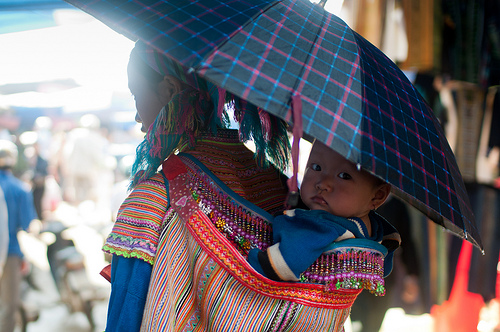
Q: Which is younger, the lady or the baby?
A: The baby is younger than the lady.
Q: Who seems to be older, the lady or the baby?
A: The lady is older than the baby.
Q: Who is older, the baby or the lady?
A: The lady is older than the baby.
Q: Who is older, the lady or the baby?
A: The lady is older than the baby.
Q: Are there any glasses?
A: No, there are no glasses.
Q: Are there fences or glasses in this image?
A: No, there are no glasses or fences.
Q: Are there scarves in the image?
A: Yes, there is a scarf.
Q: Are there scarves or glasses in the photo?
A: Yes, there is a scarf.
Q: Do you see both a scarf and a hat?
A: No, there is a scarf but no hats.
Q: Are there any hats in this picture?
A: No, there are no hats.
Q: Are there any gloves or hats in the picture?
A: No, there are no hats or gloves.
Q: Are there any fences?
A: No, there are no fences.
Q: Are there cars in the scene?
A: No, there are no cars.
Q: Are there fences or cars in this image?
A: No, there are no cars or fences.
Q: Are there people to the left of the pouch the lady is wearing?
A: Yes, there are people to the left of the pouch.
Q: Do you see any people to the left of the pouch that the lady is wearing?
A: Yes, there are people to the left of the pouch.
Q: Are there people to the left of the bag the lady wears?
A: Yes, there are people to the left of the pouch.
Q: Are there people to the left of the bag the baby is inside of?
A: Yes, there are people to the left of the bag.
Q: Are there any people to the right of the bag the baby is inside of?
A: No, the people are to the left of the bag.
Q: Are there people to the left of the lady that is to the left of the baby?
A: Yes, there are people to the left of the lady.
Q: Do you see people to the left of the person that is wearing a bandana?
A: Yes, there are people to the left of the lady.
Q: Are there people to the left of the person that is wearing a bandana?
A: Yes, there are people to the left of the lady.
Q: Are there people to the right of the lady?
A: No, the people are to the left of the lady.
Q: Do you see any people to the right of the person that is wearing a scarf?
A: No, the people are to the left of the lady.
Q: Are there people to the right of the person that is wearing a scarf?
A: No, the people are to the left of the lady.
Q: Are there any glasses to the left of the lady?
A: No, there are people to the left of the lady.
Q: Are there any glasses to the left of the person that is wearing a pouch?
A: No, there are people to the left of the lady.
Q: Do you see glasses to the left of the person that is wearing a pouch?
A: No, there are people to the left of the lady.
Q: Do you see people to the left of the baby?
A: Yes, there are people to the left of the baby.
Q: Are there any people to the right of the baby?
A: No, the people are to the left of the baby.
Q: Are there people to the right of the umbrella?
A: No, the people are to the left of the umbrella.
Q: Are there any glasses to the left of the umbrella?
A: No, there are people to the left of the umbrella.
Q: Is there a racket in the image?
A: No, there are no rackets.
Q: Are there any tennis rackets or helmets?
A: No, there are no tennis rackets or helmets.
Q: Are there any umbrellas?
A: Yes, there is an umbrella.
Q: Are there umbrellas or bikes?
A: Yes, there is an umbrella.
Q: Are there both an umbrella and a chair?
A: No, there is an umbrella but no chairs.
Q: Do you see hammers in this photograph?
A: No, there are no hammers.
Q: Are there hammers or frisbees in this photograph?
A: No, there are no hammers or frisbees.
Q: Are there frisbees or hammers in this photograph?
A: No, there are no hammers or frisbees.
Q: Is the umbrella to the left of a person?
A: No, the umbrella is to the right of a person.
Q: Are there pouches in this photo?
A: Yes, there is a pouch.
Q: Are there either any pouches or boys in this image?
A: Yes, there is a pouch.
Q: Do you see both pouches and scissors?
A: No, there is a pouch but no scissors.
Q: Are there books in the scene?
A: No, there are no books.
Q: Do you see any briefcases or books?
A: No, there are no books or briefcases.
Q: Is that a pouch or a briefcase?
A: That is a pouch.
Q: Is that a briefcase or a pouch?
A: That is a pouch.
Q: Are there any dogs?
A: No, there are no dogs.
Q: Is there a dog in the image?
A: No, there are no dogs.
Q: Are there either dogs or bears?
A: No, there are no dogs or bears.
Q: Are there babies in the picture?
A: Yes, there is a baby.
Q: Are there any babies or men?
A: Yes, there is a baby.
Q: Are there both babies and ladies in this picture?
A: Yes, there are both a baby and a lady.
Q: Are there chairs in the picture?
A: No, there are no chairs.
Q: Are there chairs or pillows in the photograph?
A: No, there are no chairs or pillows.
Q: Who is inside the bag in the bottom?
A: The baby is inside the bag.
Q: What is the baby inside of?
A: The baby is inside the bag.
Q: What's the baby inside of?
A: The baby is inside the bag.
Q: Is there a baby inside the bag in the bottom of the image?
A: Yes, there is a baby inside the bag.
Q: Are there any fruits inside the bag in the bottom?
A: No, there is a baby inside the bag.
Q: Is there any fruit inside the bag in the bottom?
A: No, there is a baby inside the bag.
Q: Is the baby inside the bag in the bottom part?
A: Yes, the baby is inside the bag.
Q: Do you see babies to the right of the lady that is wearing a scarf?
A: Yes, there is a baby to the right of the lady.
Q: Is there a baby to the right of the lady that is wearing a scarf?
A: Yes, there is a baby to the right of the lady.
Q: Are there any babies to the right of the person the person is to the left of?
A: Yes, there is a baby to the right of the lady.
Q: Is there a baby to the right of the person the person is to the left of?
A: Yes, there is a baby to the right of the lady.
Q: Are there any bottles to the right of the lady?
A: No, there is a baby to the right of the lady.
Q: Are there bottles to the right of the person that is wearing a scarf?
A: No, there is a baby to the right of the lady.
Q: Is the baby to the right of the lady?
A: Yes, the baby is to the right of the lady.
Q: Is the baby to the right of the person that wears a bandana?
A: Yes, the baby is to the right of the lady.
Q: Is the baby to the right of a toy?
A: No, the baby is to the right of the lady.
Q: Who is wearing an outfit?
A: The baby is wearing an outfit.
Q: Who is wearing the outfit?
A: The baby is wearing an outfit.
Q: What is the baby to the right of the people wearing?
A: The baby is wearing an outfit.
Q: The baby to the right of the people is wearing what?
A: The baby is wearing an outfit.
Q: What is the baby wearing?
A: The baby is wearing an outfit.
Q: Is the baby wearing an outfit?
A: Yes, the baby is wearing an outfit.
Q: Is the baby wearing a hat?
A: No, the baby is wearing an outfit.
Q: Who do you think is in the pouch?
A: The baby is in the pouch.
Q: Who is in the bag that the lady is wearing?
A: The baby is in the pouch.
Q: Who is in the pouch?
A: The baby is in the pouch.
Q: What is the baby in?
A: The baby is in the pouch.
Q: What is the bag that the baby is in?
A: The bag is a pouch.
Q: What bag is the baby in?
A: The baby is in the pouch.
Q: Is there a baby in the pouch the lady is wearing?
A: Yes, there is a baby in the pouch.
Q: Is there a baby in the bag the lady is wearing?
A: Yes, there is a baby in the pouch.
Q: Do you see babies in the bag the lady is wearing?
A: Yes, there is a baby in the pouch.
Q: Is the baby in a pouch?
A: Yes, the baby is in a pouch.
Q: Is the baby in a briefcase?
A: No, the baby is in a pouch.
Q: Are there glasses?
A: No, there are no glasses.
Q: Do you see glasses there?
A: No, there are no glasses.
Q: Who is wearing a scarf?
A: The lady is wearing a scarf.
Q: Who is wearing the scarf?
A: The lady is wearing a scarf.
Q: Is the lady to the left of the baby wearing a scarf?
A: Yes, the lady is wearing a scarf.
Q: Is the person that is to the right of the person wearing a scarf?
A: Yes, the lady is wearing a scarf.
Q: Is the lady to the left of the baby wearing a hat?
A: No, the lady is wearing a scarf.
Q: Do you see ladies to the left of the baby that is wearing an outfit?
A: Yes, there is a lady to the left of the baby.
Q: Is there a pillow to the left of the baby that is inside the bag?
A: No, there is a lady to the left of the baby.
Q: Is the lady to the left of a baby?
A: Yes, the lady is to the left of a baby.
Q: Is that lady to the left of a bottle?
A: No, the lady is to the left of a baby.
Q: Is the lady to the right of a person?
A: Yes, the lady is to the right of a person.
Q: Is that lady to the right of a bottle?
A: No, the lady is to the right of a person.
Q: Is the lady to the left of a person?
A: No, the lady is to the right of a person.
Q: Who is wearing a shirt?
A: The lady is wearing a shirt.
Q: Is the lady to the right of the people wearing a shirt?
A: Yes, the lady is wearing a shirt.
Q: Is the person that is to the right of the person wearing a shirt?
A: Yes, the lady is wearing a shirt.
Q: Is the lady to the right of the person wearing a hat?
A: No, the lady is wearing a shirt.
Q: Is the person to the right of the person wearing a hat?
A: No, the lady is wearing a shirt.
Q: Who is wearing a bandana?
A: The lady is wearing a bandana.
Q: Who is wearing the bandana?
A: The lady is wearing a bandana.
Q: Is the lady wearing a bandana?
A: Yes, the lady is wearing a bandana.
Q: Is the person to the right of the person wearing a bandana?
A: Yes, the lady is wearing a bandana.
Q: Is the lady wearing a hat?
A: No, the lady is wearing a bandana.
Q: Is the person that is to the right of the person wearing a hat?
A: No, the lady is wearing a bandana.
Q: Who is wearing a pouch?
A: The lady is wearing a pouch.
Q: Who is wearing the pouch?
A: The lady is wearing a pouch.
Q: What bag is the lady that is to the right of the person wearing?
A: The lady is wearing a pouch.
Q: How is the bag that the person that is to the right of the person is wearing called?
A: The bag is a pouch.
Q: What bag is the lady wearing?
A: The lady is wearing a pouch.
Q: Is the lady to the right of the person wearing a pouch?
A: Yes, the lady is wearing a pouch.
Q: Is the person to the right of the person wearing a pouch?
A: Yes, the lady is wearing a pouch.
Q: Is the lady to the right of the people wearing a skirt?
A: No, the lady is wearing a pouch.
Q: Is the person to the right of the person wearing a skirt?
A: No, the lady is wearing a pouch.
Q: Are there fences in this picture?
A: No, there are no fences.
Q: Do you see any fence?
A: No, there are no fences.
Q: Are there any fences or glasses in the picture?
A: No, there are no fences or glasses.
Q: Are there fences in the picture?
A: No, there are no fences.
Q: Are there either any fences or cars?
A: No, there are no fences or cars.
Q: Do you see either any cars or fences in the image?
A: No, there are no fences or cars.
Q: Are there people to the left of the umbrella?
A: Yes, there is a person to the left of the umbrella.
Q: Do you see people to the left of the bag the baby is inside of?
A: Yes, there is a person to the left of the bag.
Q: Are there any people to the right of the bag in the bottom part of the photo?
A: No, the person is to the left of the bag.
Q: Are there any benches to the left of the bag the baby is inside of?
A: No, there is a person to the left of the bag.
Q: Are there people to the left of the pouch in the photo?
A: Yes, there is a person to the left of the pouch.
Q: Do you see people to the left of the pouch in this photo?
A: Yes, there is a person to the left of the pouch.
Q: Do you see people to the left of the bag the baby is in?
A: Yes, there is a person to the left of the pouch.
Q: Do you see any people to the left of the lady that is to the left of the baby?
A: Yes, there is a person to the left of the lady.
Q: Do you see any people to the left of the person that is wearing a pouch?
A: Yes, there is a person to the left of the lady.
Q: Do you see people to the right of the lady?
A: No, the person is to the left of the lady.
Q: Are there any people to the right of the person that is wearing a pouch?
A: No, the person is to the left of the lady.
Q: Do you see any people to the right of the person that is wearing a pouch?
A: No, the person is to the left of the lady.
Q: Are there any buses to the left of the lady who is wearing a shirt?
A: No, there is a person to the left of the lady.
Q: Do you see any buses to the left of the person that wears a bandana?
A: No, there is a person to the left of the lady.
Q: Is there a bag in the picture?
A: Yes, there is a bag.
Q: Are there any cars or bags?
A: Yes, there is a bag.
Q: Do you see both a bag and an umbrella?
A: Yes, there are both a bag and an umbrella.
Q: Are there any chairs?
A: No, there are no chairs.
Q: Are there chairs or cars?
A: No, there are no chairs or cars.